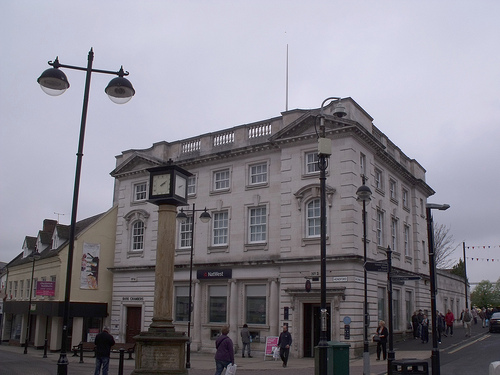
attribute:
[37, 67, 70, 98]
light — globe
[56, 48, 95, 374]
post — black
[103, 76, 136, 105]
light — globe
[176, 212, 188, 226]
light — globe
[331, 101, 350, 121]
light — black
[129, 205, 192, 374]
tower — wood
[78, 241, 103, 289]
banner — yellow, hanging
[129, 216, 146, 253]
window — big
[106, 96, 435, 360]
building — large, big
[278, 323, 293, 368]
person — walking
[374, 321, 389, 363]
person — walking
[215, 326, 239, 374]
person — walking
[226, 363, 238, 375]
bag — white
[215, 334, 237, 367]
jacket — purple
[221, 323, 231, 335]
hair — brown, short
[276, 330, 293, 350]
jacket — black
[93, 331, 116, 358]
jacket — black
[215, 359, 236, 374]
jeans — blue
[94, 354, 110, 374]
jeans — blue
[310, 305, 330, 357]
door — black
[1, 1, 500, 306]
sky — gloomy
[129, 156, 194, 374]
statue — clock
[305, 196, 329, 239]
window — big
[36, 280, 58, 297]
banner — pink